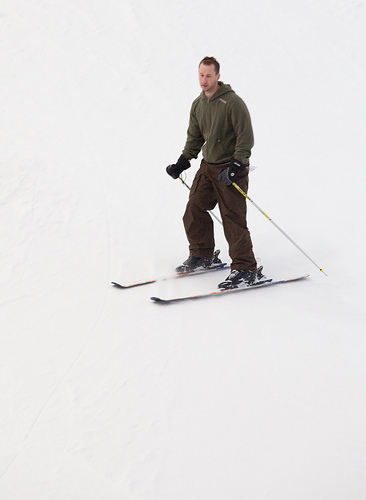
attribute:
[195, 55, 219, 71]
hair — brown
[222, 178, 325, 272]
pole — w/ yellow tip 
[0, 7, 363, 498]
snow — bright, white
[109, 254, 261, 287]
ski — colorful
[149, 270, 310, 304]
ski — colorful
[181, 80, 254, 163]
sweatshirt — khaki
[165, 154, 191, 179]
glove — black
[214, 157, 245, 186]
glove — black